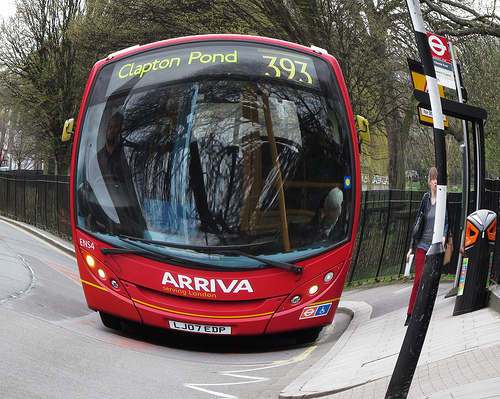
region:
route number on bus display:
[258, 50, 318, 85]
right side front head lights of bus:
[77, 246, 119, 294]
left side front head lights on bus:
[289, 271, 336, 304]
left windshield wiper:
[204, 236, 304, 272]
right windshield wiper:
[100, 241, 215, 262]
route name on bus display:
[112, 51, 241, 75]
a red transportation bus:
[59, 33, 373, 335]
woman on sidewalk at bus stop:
[401, 167, 453, 324]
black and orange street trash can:
[454, 206, 499, 313]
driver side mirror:
[351, 110, 371, 144]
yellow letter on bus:
[116, 60, 131, 78]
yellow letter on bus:
[129, 61, 135, 78]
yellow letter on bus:
[133, 60, 140, 75]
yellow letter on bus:
[140, 60, 150, 80]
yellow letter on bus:
[151, 57, 160, 71]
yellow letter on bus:
[159, 58, 170, 69]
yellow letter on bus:
[167, 55, 182, 67]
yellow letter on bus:
[186, 48, 203, 65]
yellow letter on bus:
[198, 52, 213, 65]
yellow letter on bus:
[210, 50, 226, 64]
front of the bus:
[62, 37, 350, 355]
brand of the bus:
[144, 256, 256, 295]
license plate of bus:
[155, 305, 235, 336]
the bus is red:
[111, 257, 153, 282]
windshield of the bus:
[91, 103, 316, 252]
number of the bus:
[267, 54, 324, 83]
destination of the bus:
[110, 48, 257, 70]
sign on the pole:
[419, 34, 445, 90]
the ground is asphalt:
[8, 355, 97, 389]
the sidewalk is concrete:
[332, 344, 369, 385]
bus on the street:
[55, 31, 368, 353]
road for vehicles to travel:
[6, 244, 57, 386]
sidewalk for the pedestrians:
[373, 316, 472, 381]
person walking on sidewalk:
[405, 160, 457, 338]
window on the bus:
[96, 108, 333, 228]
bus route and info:
[113, 46, 322, 92]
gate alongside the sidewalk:
[1, 165, 68, 225]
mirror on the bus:
[346, 109, 377, 142]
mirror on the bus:
[51, 105, 77, 152]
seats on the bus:
[247, 135, 323, 186]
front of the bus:
[4, 15, 348, 357]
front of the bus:
[34, 23, 344, 358]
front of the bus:
[27, 6, 342, 353]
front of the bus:
[50, 25, 336, 357]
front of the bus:
[30, 20, 344, 361]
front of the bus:
[58, 20, 351, 354]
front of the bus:
[15, 13, 360, 353]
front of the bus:
[50, 36, 357, 348]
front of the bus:
[31, 25, 363, 347]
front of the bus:
[21, 37, 354, 349]